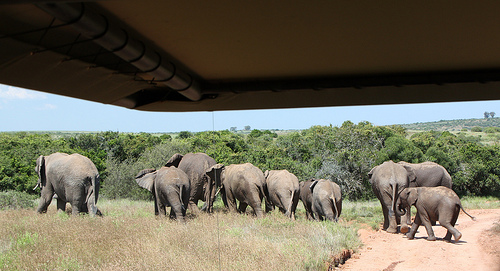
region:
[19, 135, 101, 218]
large gray elephant walking slowly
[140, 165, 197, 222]
large gray elephant walking slowly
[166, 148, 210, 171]
large gray elephant walking slowly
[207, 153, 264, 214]
large gray elephant walking slowly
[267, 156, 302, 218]
large gray elephant walking slowly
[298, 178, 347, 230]
large gray elephant walking slowly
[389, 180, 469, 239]
large gray elephant walking slowly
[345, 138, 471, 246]
large gray elephant walking slowly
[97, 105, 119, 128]
white clouds in blue sky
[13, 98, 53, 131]
white cloud in blue sky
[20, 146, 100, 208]
large gray elephant walking slowly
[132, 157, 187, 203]
large gray elephant walking slowly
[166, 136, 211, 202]
large gray elephant walking slowly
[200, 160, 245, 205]
large gray elephant walking slowly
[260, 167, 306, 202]
large gray elephant walking slowly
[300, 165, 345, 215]
large gray elephant walking slowly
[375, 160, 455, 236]
large gray elephant walking slowly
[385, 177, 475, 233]
large gray elephant walking slowly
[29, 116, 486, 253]
elephants in a field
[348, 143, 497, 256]
elephants crossing a road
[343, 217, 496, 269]
the road is unpaved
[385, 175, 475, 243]
small elephant crossing a road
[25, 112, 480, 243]
trees behind the elephants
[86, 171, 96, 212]
the tail of elephant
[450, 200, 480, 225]
the tail of elephant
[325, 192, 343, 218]
the tail of elephant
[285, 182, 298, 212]
the tail of elephant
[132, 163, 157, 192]
the ear of elephant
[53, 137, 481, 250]
herd of large elephants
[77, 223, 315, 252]
green and brown grass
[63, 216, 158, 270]
tall and wispy grass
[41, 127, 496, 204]
large forest of trees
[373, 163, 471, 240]
young elephant on path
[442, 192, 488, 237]
elephant has short tail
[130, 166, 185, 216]
elephant has large ears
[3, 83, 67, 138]
white and blue sky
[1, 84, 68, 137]
wispy clouds in sky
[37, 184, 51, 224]
leg of an elephant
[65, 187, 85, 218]
leg of an elephant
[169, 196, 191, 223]
leg of an elephant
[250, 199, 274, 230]
leg of an elephant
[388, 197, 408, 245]
leg of an elephant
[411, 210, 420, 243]
leg of an elephant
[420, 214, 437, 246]
leg of an elephant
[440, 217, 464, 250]
leg of an elephant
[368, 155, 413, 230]
a large grey elephant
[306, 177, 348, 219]
a large grey elephant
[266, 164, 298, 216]
a large grey elephant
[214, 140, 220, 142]
A green leaf on a plant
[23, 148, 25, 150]
A green leaf on a plant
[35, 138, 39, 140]
A green leaf on a plant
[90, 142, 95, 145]
A green leaf on a plant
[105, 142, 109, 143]
A green leaf on a plant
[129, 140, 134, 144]
A green leaf on a plant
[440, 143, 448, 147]
A green leaf on a plant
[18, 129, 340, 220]
elephants walking on the grass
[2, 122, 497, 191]
trees behind the elephants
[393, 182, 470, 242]
young elephant swinging his tail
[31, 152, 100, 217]
elephant leading the herd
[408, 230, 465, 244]
shadow of the small elephant on the path